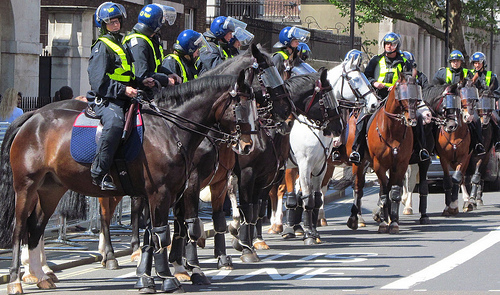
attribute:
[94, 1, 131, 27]
helmet — blue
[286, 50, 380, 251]
horse — white, standing, beautiful, standing still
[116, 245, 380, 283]
paint — white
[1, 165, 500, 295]
street — grey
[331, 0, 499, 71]
tree — split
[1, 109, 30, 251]
tail — black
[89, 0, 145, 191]
man — policeman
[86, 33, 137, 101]
jacket — blue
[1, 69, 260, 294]
horse — brown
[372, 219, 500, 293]
line — white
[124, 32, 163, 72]
stripe — neon, yellow, reflective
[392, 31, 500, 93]
columns — white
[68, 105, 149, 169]
padding — grey, red, blue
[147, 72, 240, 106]
mane — brown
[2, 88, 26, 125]
person — walking